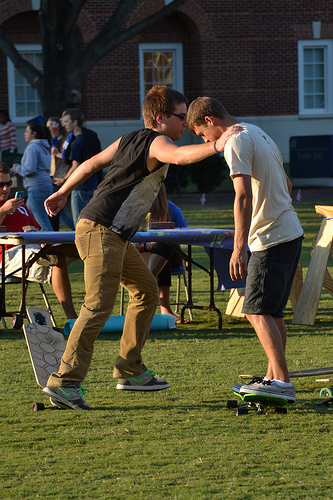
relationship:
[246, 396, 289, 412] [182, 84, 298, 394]
skateboard under man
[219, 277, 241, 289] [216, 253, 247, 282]
phone in hand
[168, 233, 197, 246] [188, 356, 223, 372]
table on grass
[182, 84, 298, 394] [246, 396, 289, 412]
man on skateboard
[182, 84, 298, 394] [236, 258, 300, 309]
man wearing shorts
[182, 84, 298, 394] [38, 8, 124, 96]
man near tree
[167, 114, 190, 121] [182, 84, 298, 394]
glasses of man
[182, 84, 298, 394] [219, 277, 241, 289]
man looking at phone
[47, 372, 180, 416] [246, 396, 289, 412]
shoes on skateboard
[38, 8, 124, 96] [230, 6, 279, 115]
tree in front of building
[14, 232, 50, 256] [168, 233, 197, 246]
tablecloth on table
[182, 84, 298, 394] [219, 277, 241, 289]
man using phone